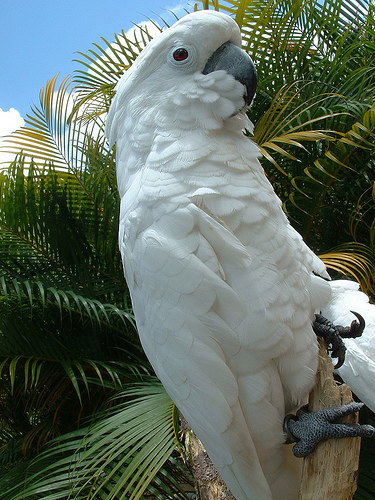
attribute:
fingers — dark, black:
[275, 393, 374, 457]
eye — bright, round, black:
[169, 45, 191, 66]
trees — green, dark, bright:
[4, 3, 373, 498]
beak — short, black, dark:
[201, 39, 260, 106]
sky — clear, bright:
[4, 4, 223, 163]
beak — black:
[201, 31, 267, 118]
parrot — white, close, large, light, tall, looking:
[102, 4, 373, 489]